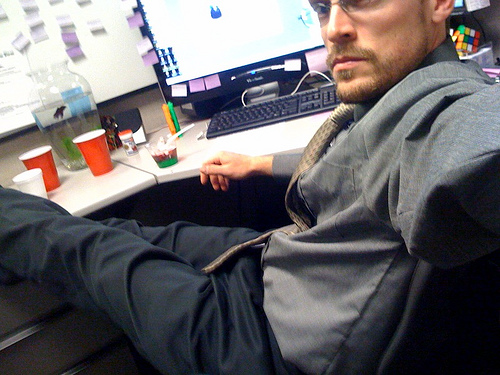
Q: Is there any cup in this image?
A: Yes, there is a cup.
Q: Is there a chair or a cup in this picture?
A: Yes, there is a cup.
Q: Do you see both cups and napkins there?
A: No, there is a cup but no napkins.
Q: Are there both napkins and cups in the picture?
A: No, there is a cup but no napkins.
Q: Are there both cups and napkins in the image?
A: No, there is a cup but no napkins.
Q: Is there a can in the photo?
A: No, there are no cans.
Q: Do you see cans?
A: No, there are no cans.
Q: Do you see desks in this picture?
A: Yes, there is a desk.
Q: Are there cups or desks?
A: Yes, there is a desk.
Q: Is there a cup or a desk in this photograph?
A: Yes, there is a desk.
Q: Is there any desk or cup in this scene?
A: Yes, there is a desk.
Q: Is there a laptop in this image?
A: No, there are no laptops.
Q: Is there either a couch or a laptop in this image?
A: No, there are no laptops or couches.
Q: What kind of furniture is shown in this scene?
A: The furniture is a desk.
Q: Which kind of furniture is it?
A: The piece of furniture is a desk.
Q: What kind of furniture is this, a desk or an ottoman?
A: This is a desk.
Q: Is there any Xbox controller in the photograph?
A: No, there are no Xbox controllers.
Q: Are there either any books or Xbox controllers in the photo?
A: No, there are no Xbox controllers or books.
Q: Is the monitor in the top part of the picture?
A: Yes, the monitor is in the top of the image.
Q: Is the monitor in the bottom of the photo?
A: No, the monitor is in the top of the image.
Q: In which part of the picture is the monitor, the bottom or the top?
A: The monitor is in the top of the image.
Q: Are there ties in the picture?
A: Yes, there is a tie.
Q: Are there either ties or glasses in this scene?
A: Yes, there is a tie.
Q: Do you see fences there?
A: No, there are no fences.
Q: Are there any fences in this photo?
A: No, there are no fences.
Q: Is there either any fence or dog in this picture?
A: No, there are no fences or dogs.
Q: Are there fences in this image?
A: No, there are no fences.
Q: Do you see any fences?
A: No, there are no fences.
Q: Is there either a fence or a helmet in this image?
A: No, there are no fences or helmets.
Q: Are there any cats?
A: No, there are no cats.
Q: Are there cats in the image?
A: No, there are no cats.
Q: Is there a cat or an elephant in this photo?
A: No, there are no cats or elephants.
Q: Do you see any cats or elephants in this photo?
A: No, there are no cats or elephants.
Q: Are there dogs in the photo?
A: No, there are no dogs.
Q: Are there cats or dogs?
A: No, there are no dogs or cats.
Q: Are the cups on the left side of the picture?
A: Yes, the cups are on the left of the image.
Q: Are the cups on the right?
A: No, the cups are on the left of the image.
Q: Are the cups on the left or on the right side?
A: The cups are on the left of the image.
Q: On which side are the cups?
A: The cups are on the left of the image.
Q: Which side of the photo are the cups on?
A: The cups are on the left of the image.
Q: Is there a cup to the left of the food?
A: Yes, there are cups to the left of the food.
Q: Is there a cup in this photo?
A: Yes, there is a cup.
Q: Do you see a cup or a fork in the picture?
A: Yes, there is a cup.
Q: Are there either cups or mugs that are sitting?
A: Yes, the cup is sitting.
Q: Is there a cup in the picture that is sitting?
A: Yes, there is a cup that is sitting.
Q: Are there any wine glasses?
A: No, there are no wine glasses.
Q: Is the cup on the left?
A: Yes, the cup is on the left of the image.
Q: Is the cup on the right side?
A: No, the cup is on the left of the image.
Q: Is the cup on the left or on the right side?
A: The cup is on the left of the image.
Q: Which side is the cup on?
A: The cup is on the left of the image.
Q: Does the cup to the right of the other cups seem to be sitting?
A: Yes, the cup is sitting.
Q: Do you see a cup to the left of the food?
A: Yes, there is a cup to the left of the food.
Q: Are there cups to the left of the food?
A: Yes, there is a cup to the left of the food.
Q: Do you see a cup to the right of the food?
A: No, the cup is to the left of the food.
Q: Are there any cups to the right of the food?
A: No, the cup is to the left of the food.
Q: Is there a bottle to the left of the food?
A: No, there is a cup to the left of the food.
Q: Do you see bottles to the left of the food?
A: No, there is a cup to the left of the food.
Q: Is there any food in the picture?
A: Yes, there is food.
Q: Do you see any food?
A: Yes, there is food.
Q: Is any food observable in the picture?
A: Yes, there is food.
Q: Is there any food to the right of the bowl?
A: Yes, there is food to the right of the bowl.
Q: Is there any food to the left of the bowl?
A: No, the food is to the right of the bowl.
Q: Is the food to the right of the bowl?
A: Yes, the food is to the right of the bowl.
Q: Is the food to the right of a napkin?
A: No, the food is to the right of the bowl.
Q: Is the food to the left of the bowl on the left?
A: No, the food is to the right of the bowl.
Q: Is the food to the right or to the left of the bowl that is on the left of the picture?
A: The food is to the right of the bowl.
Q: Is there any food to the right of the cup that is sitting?
A: Yes, there is food to the right of the cup.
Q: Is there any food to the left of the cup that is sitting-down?
A: No, the food is to the right of the cup.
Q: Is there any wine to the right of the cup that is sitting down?
A: No, there is food to the right of the cup.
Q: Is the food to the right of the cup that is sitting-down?
A: Yes, the food is to the right of the cup.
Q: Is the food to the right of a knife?
A: No, the food is to the right of the cup.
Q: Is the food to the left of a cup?
A: No, the food is to the right of a cup.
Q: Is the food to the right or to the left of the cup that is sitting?
A: The food is to the right of the cup.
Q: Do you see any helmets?
A: No, there are no helmets.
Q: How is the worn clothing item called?
A: The clothing item is a suit.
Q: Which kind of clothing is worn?
A: The clothing is a suit.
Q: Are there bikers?
A: No, there are no bikers.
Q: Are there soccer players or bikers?
A: No, there are no bikers or soccer players.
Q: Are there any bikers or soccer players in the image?
A: No, there are no bikers or soccer players.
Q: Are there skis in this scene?
A: No, there are no skis.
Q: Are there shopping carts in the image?
A: No, there are no shopping carts.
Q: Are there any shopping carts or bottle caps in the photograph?
A: No, there are no shopping carts or bottle caps.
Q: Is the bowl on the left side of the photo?
A: Yes, the bowl is on the left of the image.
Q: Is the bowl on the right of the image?
A: No, the bowl is on the left of the image.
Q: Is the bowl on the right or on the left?
A: The bowl is on the left of the image.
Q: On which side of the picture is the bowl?
A: The bowl is on the left of the image.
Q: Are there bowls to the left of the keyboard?
A: Yes, there is a bowl to the left of the keyboard.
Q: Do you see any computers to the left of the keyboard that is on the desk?
A: No, there is a bowl to the left of the keyboard.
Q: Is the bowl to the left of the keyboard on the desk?
A: Yes, the bowl is to the left of the keyboard.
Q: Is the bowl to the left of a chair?
A: No, the bowl is to the left of the keyboard.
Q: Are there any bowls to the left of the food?
A: Yes, there is a bowl to the left of the food.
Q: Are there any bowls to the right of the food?
A: No, the bowl is to the left of the food.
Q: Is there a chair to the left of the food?
A: No, there is a bowl to the left of the food.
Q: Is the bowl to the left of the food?
A: Yes, the bowl is to the left of the food.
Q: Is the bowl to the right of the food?
A: No, the bowl is to the left of the food.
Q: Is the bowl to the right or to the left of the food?
A: The bowl is to the left of the food.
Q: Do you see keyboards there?
A: Yes, there is a keyboard.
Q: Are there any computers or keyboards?
A: Yes, there is a keyboard.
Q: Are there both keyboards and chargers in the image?
A: No, there is a keyboard but no chargers.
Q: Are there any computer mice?
A: No, there are no computer mice.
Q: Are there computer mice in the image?
A: No, there are no computer mice.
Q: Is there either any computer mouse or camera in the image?
A: No, there are no computer mice or cameras.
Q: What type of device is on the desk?
A: The device is a keyboard.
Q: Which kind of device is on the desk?
A: The device is a keyboard.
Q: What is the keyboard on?
A: The keyboard is on the desk.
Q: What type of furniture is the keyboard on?
A: The keyboard is on the desk.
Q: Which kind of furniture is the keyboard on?
A: The keyboard is on the desk.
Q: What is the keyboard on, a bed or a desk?
A: The keyboard is on a desk.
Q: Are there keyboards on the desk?
A: Yes, there is a keyboard on the desk.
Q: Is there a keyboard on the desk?
A: Yes, there is a keyboard on the desk.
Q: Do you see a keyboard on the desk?
A: Yes, there is a keyboard on the desk.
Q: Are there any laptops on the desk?
A: No, there is a keyboard on the desk.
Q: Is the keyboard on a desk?
A: Yes, the keyboard is on a desk.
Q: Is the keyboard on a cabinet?
A: No, the keyboard is on a desk.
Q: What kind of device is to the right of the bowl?
A: The device is a keyboard.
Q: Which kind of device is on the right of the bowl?
A: The device is a keyboard.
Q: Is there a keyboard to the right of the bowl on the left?
A: Yes, there is a keyboard to the right of the bowl.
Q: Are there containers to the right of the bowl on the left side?
A: No, there is a keyboard to the right of the bowl.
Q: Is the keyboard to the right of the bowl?
A: Yes, the keyboard is to the right of the bowl.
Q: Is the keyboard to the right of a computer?
A: No, the keyboard is to the right of the bowl.